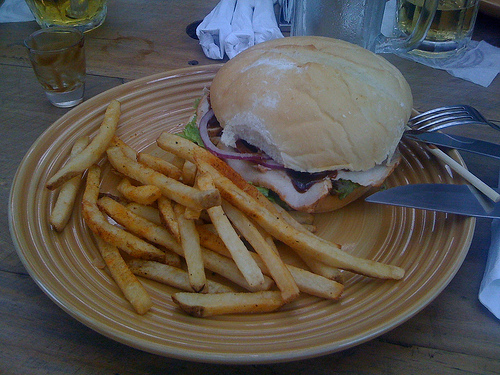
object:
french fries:
[191, 156, 406, 285]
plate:
[8, 64, 476, 367]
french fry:
[45, 100, 121, 193]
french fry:
[49, 136, 89, 231]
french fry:
[172, 289, 286, 317]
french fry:
[106, 146, 222, 210]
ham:
[222, 141, 334, 211]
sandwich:
[175, 35, 414, 214]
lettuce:
[174, 97, 359, 210]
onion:
[198, 106, 285, 170]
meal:
[46, 36, 413, 318]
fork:
[407, 105, 499, 133]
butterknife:
[401, 129, 499, 160]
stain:
[99, 35, 162, 63]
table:
[1, 1, 500, 374]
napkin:
[195, 0, 236, 61]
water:
[294, 1, 362, 33]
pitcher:
[291, 1, 439, 56]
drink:
[25, 31, 85, 94]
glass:
[23, 24, 86, 110]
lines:
[366, 296, 399, 317]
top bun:
[209, 33, 415, 172]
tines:
[408, 104, 464, 121]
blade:
[364, 183, 499, 219]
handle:
[376, 1, 438, 54]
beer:
[397, 1, 474, 39]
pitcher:
[394, 1, 479, 63]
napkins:
[478, 192, 500, 320]